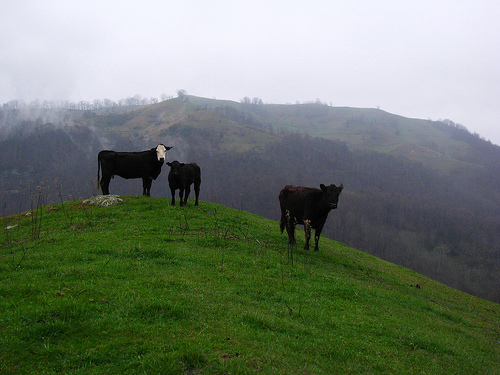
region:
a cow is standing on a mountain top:
[85, 137, 175, 236]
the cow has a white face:
[146, 140, 172, 162]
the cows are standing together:
[91, 129, 206, 219]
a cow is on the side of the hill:
[268, 174, 347, 251]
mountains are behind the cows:
[1, 90, 498, 329]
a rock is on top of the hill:
[78, 191, 123, 214]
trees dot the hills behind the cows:
[6, 88, 499, 308]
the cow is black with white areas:
[273, 175, 348, 258]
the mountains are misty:
[6, 13, 497, 303]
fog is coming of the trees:
[3, 37, 112, 225]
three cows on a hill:
[68, 130, 361, 260]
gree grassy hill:
[3, 194, 498, 374]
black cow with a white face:
[88, 133, 173, 200]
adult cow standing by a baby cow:
[91, 136, 220, 203]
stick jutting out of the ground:
[276, 256, 288, 293]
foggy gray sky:
[0, 2, 499, 146]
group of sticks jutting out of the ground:
[16, 186, 57, 240]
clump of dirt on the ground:
[413, 282, 425, 291]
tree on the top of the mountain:
[240, 92, 251, 109]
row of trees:
[2, 92, 157, 110]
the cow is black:
[263, 152, 350, 247]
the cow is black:
[269, 122, 370, 292]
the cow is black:
[280, 161, 418, 312]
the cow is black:
[272, 180, 350, 284]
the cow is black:
[262, 128, 327, 312]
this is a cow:
[272, 178, 349, 248]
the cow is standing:
[272, 177, 349, 248]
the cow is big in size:
[93, 139, 168, 201]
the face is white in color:
[152, 144, 164, 159]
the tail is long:
[95, 165, 102, 186]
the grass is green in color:
[76, 267, 263, 372]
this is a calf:
[166, 155, 211, 207]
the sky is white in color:
[170, 12, 262, 52]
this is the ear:
[319, 182, 326, 189]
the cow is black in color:
[113, 156, 148, 174]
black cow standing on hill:
[251, 176, 345, 263]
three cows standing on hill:
[71, 105, 365, 267]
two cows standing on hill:
[94, 134, 215, 221]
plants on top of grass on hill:
[19, 186, 84, 268]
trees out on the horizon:
[7, 90, 207, 127]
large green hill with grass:
[33, 107, 457, 370]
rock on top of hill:
[84, 186, 147, 213]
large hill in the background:
[33, 71, 482, 218]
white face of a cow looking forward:
[153, 142, 171, 162]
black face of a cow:
[314, 180, 348, 211]